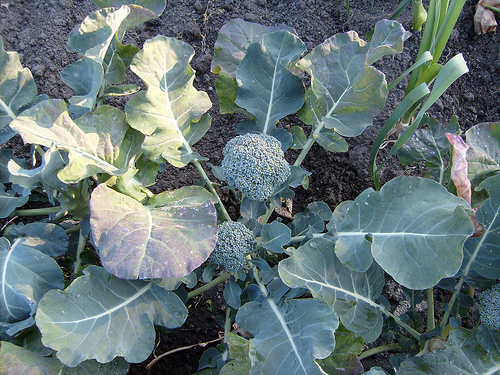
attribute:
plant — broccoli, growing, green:
[4, 1, 498, 373]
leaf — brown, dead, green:
[472, 4, 496, 36]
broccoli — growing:
[220, 130, 291, 201]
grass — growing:
[411, 2, 466, 102]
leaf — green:
[299, 20, 410, 136]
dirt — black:
[2, 0, 499, 373]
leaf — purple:
[92, 184, 220, 282]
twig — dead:
[147, 335, 222, 366]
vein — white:
[294, 85, 348, 166]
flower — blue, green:
[441, 133, 481, 232]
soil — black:
[3, 0, 497, 371]